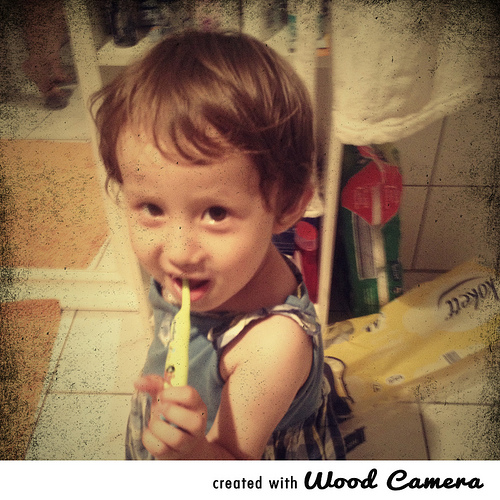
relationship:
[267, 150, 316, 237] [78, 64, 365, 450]
ear of child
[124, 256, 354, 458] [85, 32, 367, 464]
dress on girl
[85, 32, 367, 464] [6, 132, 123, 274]
girl behind rug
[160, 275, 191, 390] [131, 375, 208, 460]
brush in hand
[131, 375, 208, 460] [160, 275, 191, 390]
hand on brush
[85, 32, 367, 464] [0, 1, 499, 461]
girl standing in bathroom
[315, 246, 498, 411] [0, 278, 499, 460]
bag on floor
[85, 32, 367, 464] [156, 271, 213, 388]
girl holding toothbrush